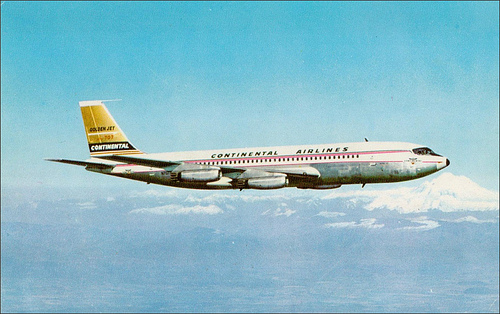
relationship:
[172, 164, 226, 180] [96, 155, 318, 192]
engine on wing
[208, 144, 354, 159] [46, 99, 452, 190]
logo on airplane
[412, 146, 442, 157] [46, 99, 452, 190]
windshield of airplane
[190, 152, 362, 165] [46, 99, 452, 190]
windows on airplane